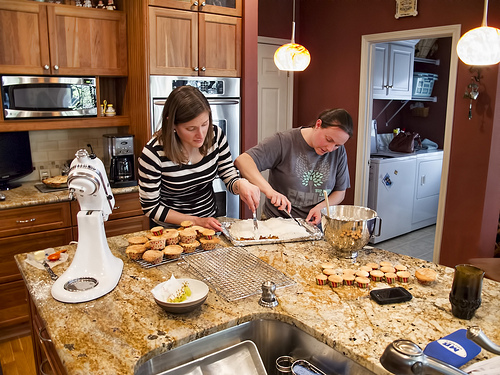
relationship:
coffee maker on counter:
[102, 132, 138, 187] [2, 180, 141, 210]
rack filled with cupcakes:
[120, 237, 225, 277] [124, 219, 218, 264]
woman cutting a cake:
[138, 83, 261, 230] [225, 217, 307, 239]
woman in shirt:
[234, 109, 361, 223] [239, 123, 352, 229]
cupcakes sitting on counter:
[315, 259, 432, 283] [13, 214, 499, 374]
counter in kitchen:
[2, 161, 143, 215] [4, 3, 497, 372]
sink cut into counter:
[129, 313, 385, 374] [13, 214, 499, 374]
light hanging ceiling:
[456, 4, 494, 68] [2, 0, 493, 25]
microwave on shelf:
[1, 74, 96, 119] [0, 74, 127, 132]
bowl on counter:
[320, 205, 383, 261] [13, 214, 499, 374]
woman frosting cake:
[241, 109, 362, 224] [228, 216, 309, 243]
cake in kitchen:
[228, 216, 309, 243] [4, 3, 497, 372]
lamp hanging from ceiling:
[269, 0, 312, 77] [0, 0, 500, 24]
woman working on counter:
[138, 83, 261, 230] [13, 214, 499, 374]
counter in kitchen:
[13, 214, 499, 374] [4, 3, 497, 372]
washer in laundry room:
[366, 144, 414, 245] [365, 34, 457, 258]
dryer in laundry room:
[417, 144, 443, 229] [365, 34, 457, 258]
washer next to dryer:
[370, 120, 415, 245] [388, 131, 443, 231]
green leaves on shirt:
[302, 165, 323, 188] [245, 125, 349, 216]